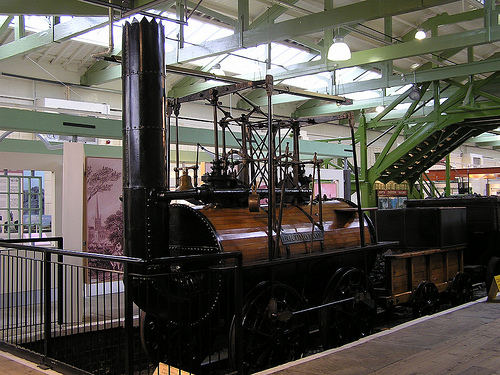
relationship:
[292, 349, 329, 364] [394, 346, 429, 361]
lines in pathway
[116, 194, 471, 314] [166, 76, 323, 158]
train in shed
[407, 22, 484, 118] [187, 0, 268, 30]
beams on ceiling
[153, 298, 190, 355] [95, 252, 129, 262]
poles on rail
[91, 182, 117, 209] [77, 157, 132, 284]
picture in frame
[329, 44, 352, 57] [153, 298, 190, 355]
lights on poles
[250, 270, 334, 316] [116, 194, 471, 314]
engine on train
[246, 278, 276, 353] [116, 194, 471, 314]
wheel of train